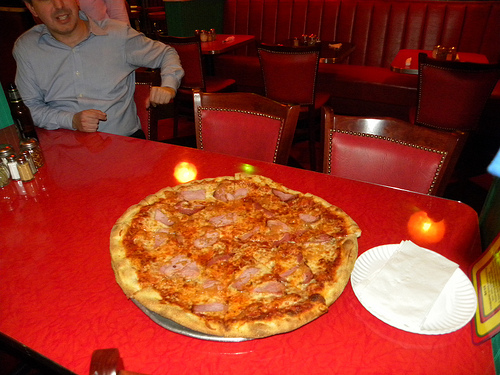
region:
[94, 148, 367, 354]
Huge pizza on the table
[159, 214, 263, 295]
Meat on the pizza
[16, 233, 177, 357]
The table top is red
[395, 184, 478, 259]
Light reflection on the table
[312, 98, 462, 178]
The chair is wood with cloth padding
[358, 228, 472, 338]
Paper plates and napkins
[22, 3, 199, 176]
Man looking at the pizza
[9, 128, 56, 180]
Spices on the table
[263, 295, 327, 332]
The crust is golden brown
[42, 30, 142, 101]
Man wearing a long sleeve shirt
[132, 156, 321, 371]
large pizza on platter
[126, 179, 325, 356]
platter on red table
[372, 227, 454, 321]
white paper plates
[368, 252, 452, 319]
white napkins on paper plates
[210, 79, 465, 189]
red and brown chairs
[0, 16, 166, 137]
man has grey shirt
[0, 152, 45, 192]
salt and pepper shakers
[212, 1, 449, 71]
brown wall behind table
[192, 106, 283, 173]
red back on chair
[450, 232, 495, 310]
menu at end of table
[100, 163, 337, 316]
large pizza on red table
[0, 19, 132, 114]
man sitting at dinner table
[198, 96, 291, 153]
red chair near table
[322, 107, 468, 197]
red chair near table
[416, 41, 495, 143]
red chair near table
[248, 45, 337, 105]
red chair near table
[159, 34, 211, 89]
red chair near table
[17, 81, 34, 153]
beer bottle on table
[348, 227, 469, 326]
white paper plate on right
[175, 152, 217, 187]
light reflecting off table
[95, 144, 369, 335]
a large pizza on a red table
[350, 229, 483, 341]
a plate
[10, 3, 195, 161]
person wearing a dress shirt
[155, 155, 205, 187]
reflections from the light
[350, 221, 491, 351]
a white plate on a table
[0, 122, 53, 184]
spices and pepper on table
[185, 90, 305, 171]
a red wooden chair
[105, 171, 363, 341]
a whole pizza on a steel plate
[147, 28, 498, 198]
bunch of chairs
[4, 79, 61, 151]
bottle of beer on table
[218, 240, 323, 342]
triangle slice of pizza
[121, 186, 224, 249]
triangle slice of pizza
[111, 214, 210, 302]
triangle slice of pizza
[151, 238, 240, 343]
triangle slice of pizza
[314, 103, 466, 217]
red chair at table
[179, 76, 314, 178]
red chair at table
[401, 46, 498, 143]
red chair at table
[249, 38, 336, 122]
red chair at table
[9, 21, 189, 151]
man wearing a blue shirt